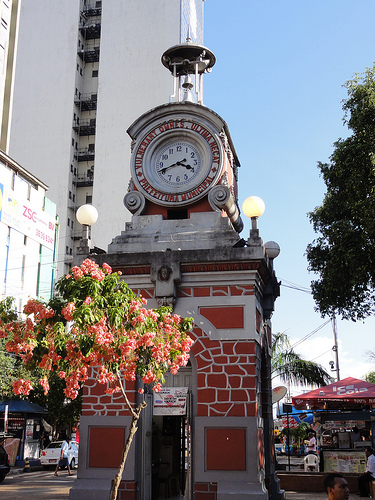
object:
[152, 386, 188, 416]
banner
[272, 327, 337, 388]
frond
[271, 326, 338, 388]
tree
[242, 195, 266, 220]
light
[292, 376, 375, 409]
tent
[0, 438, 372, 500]
street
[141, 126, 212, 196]
clock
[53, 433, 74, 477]
woman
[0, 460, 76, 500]
ground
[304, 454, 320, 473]
chair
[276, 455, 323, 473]
sidewalk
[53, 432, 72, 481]
man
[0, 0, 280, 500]
building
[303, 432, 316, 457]
person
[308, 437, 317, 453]
shirt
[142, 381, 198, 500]
door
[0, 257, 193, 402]
blossoms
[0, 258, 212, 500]
tree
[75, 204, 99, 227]
lights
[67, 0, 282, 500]
monument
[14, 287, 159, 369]
branch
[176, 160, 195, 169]
hand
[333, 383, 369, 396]
ice cola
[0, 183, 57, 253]
billboard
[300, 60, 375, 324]
leaves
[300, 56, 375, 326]
tree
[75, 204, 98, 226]
light globe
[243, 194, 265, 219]
light globe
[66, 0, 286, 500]
brick tower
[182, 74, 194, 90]
bell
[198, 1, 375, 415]
sky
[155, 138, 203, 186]
clock face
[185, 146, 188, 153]
number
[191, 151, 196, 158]
number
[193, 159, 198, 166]
number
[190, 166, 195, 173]
number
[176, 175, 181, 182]
number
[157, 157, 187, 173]
hands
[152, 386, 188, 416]
poster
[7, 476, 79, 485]
lines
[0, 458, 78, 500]
road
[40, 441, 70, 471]
car